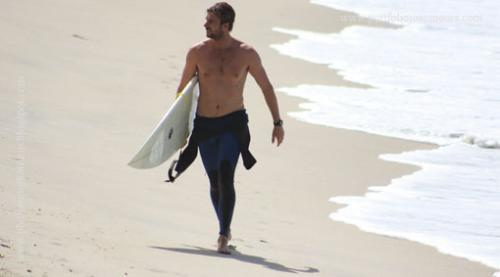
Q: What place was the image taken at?
A: It was taken at the beach.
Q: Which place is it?
A: It is a beach.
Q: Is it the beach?
A: Yes, it is the beach.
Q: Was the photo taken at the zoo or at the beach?
A: It was taken at the beach.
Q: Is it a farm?
A: No, it is a beach.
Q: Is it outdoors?
A: Yes, it is outdoors.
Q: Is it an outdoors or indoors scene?
A: It is outdoors.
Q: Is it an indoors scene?
A: No, it is outdoors.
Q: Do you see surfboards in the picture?
A: Yes, there is a surfboard.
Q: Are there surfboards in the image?
A: Yes, there is a surfboard.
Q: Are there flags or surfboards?
A: Yes, there is a surfboard.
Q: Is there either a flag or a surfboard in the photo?
A: Yes, there is a surfboard.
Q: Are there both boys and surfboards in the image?
A: No, there is a surfboard but no boys.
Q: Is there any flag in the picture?
A: No, there are no flags.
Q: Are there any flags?
A: No, there are no flags.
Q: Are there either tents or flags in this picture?
A: No, there are no flags or tents.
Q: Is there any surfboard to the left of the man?
A: Yes, there is a surfboard to the left of the man.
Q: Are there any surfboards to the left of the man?
A: Yes, there is a surfboard to the left of the man.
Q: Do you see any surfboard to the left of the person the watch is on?
A: Yes, there is a surfboard to the left of the man.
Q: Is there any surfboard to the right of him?
A: No, the surfboard is to the left of the man.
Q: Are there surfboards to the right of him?
A: No, the surfboard is to the left of the man.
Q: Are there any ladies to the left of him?
A: No, there is a surfboard to the left of the man.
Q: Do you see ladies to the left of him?
A: No, there is a surfboard to the left of the man.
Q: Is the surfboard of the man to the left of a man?
A: Yes, the surfboard is to the left of a man.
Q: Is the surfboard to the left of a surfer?
A: No, the surfboard is to the left of a man.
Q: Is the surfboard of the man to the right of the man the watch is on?
A: No, the surfboard is to the left of the man.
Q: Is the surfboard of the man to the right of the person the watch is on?
A: No, the surfboard is to the left of the man.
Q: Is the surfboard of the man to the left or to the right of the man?
A: The surfboard is to the left of the man.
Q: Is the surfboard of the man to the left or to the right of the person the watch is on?
A: The surfboard is to the left of the man.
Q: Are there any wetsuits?
A: Yes, there is a wetsuit.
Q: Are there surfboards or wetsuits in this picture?
A: Yes, there is a wetsuit.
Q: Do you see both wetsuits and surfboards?
A: Yes, there are both a wetsuit and a surfboard.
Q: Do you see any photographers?
A: No, there are no photographers.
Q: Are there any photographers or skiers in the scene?
A: No, there are no photographers or skiers.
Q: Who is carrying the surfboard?
A: The man is carrying the surfboard.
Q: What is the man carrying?
A: The man is carrying a surfboard.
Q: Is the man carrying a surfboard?
A: Yes, the man is carrying a surfboard.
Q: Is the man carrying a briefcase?
A: No, the man is carrying a surfboard.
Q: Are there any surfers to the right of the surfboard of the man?
A: No, there is a man to the right of the surf board.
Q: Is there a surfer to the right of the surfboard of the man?
A: No, there is a man to the right of the surf board.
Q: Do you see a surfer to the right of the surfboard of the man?
A: No, there is a man to the right of the surf board.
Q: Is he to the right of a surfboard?
A: Yes, the man is to the right of a surfboard.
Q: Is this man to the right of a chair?
A: No, the man is to the right of a surfboard.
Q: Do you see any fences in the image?
A: No, there are no fences.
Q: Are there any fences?
A: No, there are no fences.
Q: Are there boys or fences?
A: No, there are no fences or boys.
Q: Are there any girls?
A: No, there are no girls.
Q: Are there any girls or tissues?
A: No, there are no girls or tissues.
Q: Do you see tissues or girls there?
A: No, there are no girls or tissues.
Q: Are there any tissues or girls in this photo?
A: No, there are no girls or tissues.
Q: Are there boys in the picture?
A: No, there are no boys.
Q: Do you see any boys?
A: No, there are no boys.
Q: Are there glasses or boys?
A: No, there are no boys or glasses.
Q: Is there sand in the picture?
A: Yes, there is sand.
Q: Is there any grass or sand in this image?
A: Yes, there is sand.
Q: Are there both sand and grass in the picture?
A: No, there is sand but no grass.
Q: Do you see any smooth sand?
A: Yes, there is smooth sand.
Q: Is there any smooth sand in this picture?
A: Yes, there is smooth sand.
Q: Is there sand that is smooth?
A: Yes, there is sand that is smooth.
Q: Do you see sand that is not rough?
A: Yes, there is smooth sand.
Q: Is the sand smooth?
A: Yes, the sand is smooth.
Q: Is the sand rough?
A: No, the sand is smooth.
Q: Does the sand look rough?
A: No, the sand is smooth.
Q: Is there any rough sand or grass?
A: No, there is sand but it is smooth.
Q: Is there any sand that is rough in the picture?
A: No, there is sand but it is smooth.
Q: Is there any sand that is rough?
A: No, there is sand but it is smooth.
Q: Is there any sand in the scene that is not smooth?
A: No, there is sand but it is smooth.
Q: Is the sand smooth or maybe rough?
A: The sand is smooth.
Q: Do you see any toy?
A: No, there are no toys.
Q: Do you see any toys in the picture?
A: No, there are no toys.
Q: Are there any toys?
A: No, there are no toys.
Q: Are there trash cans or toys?
A: No, there are no toys or trash cans.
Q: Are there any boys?
A: No, there are no boys.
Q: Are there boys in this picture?
A: No, there are no boys.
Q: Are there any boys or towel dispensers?
A: No, there are no boys or towel dispensers.